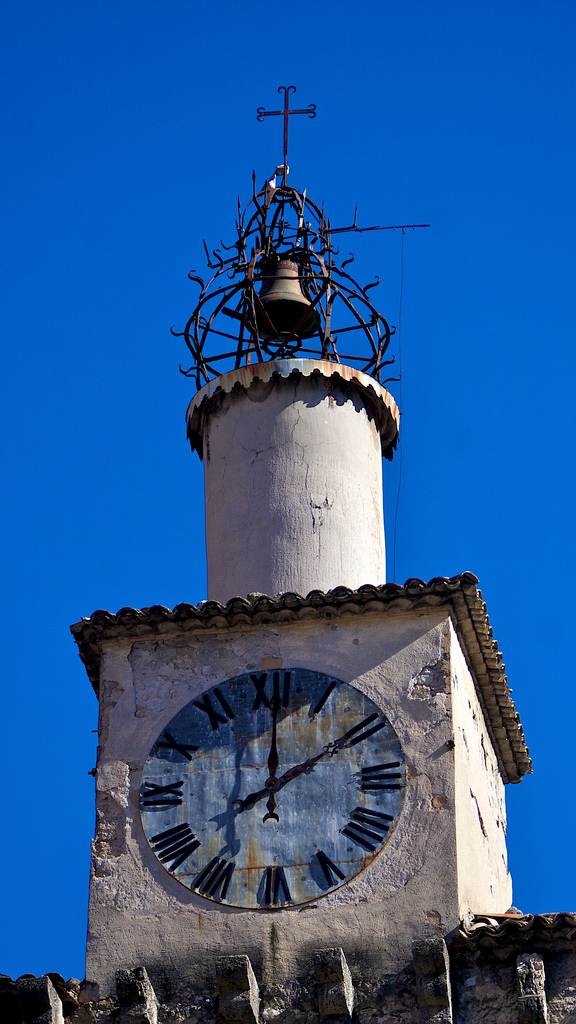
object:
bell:
[248, 260, 320, 342]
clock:
[139, 662, 410, 914]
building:
[67, 88, 533, 1014]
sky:
[0, 5, 575, 985]